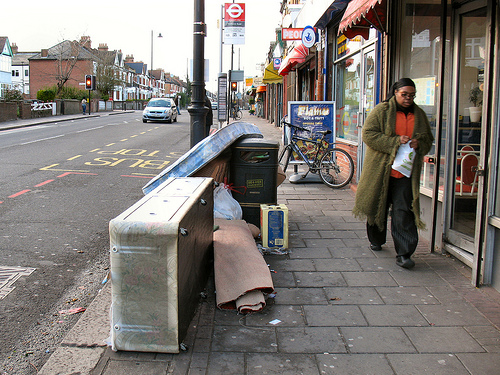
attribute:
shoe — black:
[368, 237, 384, 250]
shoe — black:
[391, 254, 413, 267]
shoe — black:
[392, 253, 419, 273]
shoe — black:
[368, 244, 382, 254]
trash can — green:
[228, 138, 287, 230]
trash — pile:
[259, 202, 292, 253]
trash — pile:
[212, 214, 273, 314]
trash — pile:
[229, 135, 279, 222]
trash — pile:
[140, 120, 263, 197]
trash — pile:
[103, 170, 216, 353]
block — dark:
[211, 323, 279, 355]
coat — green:
[355, 102, 432, 256]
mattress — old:
[158, 99, 276, 214]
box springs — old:
[107, 172, 214, 355]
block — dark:
[243, 352, 318, 372]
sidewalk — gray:
[95, 106, 498, 373]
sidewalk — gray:
[186, 63, 478, 373]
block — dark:
[264, 285, 327, 307]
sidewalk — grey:
[292, 182, 498, 372]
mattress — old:
[142, 121, 263, 194]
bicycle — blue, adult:
[277, 115, 354, 190]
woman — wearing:
[344, 71, 429, 275]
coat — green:
[353, 100, 435, 229]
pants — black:
[364, 173, 420, 263]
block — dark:
[240, 305, 310, 325]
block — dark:
[272, 285, 327, 311]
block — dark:
[284, 227, 320, 242]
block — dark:
[338, 323, 413, 354]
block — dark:
[450, 350, 497, 372]